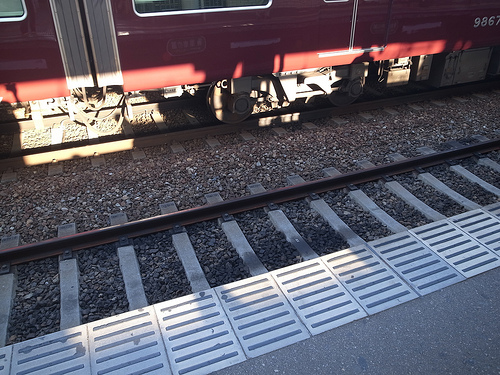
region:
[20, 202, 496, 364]
line of rectangular striped tiles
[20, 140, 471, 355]
bars underneath tiles and rail tracks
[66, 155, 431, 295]
gravel underneath tracks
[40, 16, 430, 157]
red train on tracks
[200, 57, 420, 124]
train machinery in undercarriage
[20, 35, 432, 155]
sunlight falling on lower part of train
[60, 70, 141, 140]
loops hanging under train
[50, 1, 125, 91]
two panels on top of the loops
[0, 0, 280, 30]
bottom of window rims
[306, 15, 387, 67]
perpendicular line on train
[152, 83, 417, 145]
Wheels on train track.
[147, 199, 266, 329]
Gravel by the tracks.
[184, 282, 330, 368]
Metal on the side of the track.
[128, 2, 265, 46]
Window on the train.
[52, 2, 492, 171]
Red train on the tracks.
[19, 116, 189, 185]
Tracks underneath the train.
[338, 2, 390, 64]
White stripe on the train.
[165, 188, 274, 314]
Ties on the track.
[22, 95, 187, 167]
Sunlight shining on the train.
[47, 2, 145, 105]
Grey connectors between trains.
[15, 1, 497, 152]
a train is on the tracks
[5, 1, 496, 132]
the train is red and white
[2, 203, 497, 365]
the platform is near the tracks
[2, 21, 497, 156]
the sun is shining on the train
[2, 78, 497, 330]
gravel is around the tracks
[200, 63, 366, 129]
the wheels of the train on the tracks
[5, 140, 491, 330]
the tracks closest to the platform are empty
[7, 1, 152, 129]
two train cars are connected here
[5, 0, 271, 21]
the passenger train has windows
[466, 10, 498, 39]
number markings on the train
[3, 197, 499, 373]
Silver panels at the edge of the sidewalk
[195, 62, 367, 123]
Wheels of the train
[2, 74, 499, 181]
Tracks that the train is on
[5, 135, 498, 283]
Tracks next to the train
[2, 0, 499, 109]
The red train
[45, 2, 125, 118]
Where the train cars connect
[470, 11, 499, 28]
White writing on the side of the train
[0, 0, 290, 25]
The windows of the train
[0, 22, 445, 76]
Objects reflected on the train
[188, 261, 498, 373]
Sidewalk of the platform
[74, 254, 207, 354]
Rocks between rail tracks.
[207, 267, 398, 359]
Metal grate on the road.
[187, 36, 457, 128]
Wheels on the train.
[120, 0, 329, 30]
Windows on the train.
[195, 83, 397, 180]
Track underneath the train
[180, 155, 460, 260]
Rail ties on the track.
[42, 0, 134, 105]
Connector between the trains.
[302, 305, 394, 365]
Concrete beside the track.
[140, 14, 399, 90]
White markings on red train